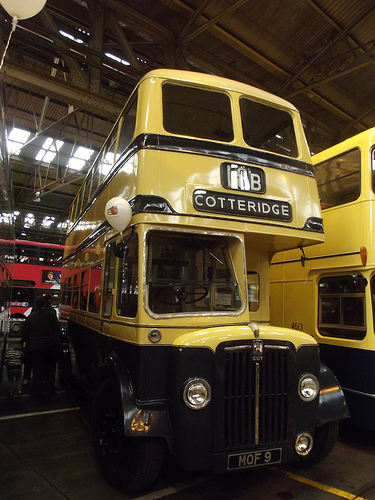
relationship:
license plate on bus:
[226, 446, 285, 473] [54, 64, 353, 494]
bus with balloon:
[54, 64, 353, 494] [104, 193, 133, 240]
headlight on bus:
[296, 370, 321, 403] [54, 64, 353, 494]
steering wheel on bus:
[152, 278, 209, 307] [54, 64, 353, 494]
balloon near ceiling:
[0, 1, 49, 21] [2, 1, 375, 156]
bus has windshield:
[54, 64, 353, 494] [141, 228, 248, 318]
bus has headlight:
[54, 64, 353, 494] [183, 376, 212, 411]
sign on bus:
[192, 187, 295, 225] [54, 64, 353, 494]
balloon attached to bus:
[104, 193, 133, 240] [54, 64, 353, 494]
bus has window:
[54, 64, 353, 494] [160, 79, 238, 144]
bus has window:
[54, 64, 353, 494] [119, 86, 140, 154]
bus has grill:
[54, 64, 353, 494] [217, 343, 294, 450]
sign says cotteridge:
[192, 187, 295, 225] [195, 195, 290, 218]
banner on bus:
[39, 267, 62, 288] [2, 235, 106, 341]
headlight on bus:
[183, 376, 212, 411] [54, 64, 353, 494]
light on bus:
[293, 432, 314, 460] [54, 64, 353, 494]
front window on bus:
[141, 228, 248, 318] [54, 64, 353, 494]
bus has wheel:
[54, 64, 353, 494] [86, 373, 164, 496]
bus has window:
[54, 64, 353, 494] [236, 94, 305, 162]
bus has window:
[54, 64, 353, 494] [114, 231, 137, 323]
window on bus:
[97, 117, 117, 185] [54, 64, 353, 494]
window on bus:
[89, 151, 101, 202] [54, 64, 353, 494]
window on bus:
[82, 170, 94, 215] [54, 64, 353, 494]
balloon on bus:
[104, 193, 133, 240] [54, 64, 353, 494]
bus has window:
[54, 64, 353, 494] [86, 254, 107, 320]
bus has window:
[54, 64, 353, 494] [77, 264, 89, 314]